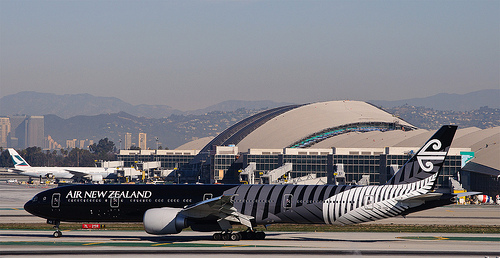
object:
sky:
[0, 0, 500, 112]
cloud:
[0, 0, 500, 113]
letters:
[64, 189, 73, 198]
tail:
[383, 124, 459, 185]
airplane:
[21, 124, 483, 242]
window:
[328, 199, 332, 203]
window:
[248, 200, 251, 202]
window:
[342, 201, 343, 203]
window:
[294, 198, 298, 202]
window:
[303, 200, 306, 203]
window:
[308, 198, 312, 202]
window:
[312, 199, 316, 203]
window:
[299, 200, 304, 204]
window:
[322, 199, 325, 202]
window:
[326, 201, 328, 203]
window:
[332, 200, 335, 203]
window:
[348, 200, 352, 204]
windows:
[203, 193, 213, 201]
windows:
[282, 193, 293, 208]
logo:
[64, 190, 153, 199]